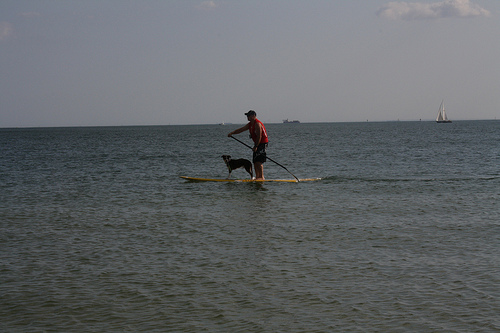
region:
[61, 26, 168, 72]
this is the sky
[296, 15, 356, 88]
the sky is blue in color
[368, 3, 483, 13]
the sky has some clouds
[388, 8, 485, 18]
the clouds are white in color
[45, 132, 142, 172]
this is the water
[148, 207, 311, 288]
the water has some ripples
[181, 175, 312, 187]
this is a surfboard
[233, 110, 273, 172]
this is a man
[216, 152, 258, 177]
this is a dog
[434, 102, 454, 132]
this is a yacht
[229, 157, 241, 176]
the dog is black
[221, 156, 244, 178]
the dog is black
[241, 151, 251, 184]
the dog is black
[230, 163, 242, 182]
the dog is black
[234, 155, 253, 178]
the dog is black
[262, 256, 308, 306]
the water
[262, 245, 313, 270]
the water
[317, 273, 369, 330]
the water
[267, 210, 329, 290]
the water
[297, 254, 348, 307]
the water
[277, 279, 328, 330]
the water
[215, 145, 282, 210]
a dog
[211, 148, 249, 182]
a dog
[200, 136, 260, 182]
a dog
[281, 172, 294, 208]
the raft is bamboo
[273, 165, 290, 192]
the raft is bamboo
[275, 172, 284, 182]
the raft is bamboo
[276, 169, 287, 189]
the raft is bamboo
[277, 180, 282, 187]
the raft is bamboo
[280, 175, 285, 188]
the raft is bamboo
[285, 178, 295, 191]
the raft is bamboo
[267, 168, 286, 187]
the raft is bamboo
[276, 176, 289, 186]
the raft is bamboo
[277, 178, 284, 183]
the raft is bamboo